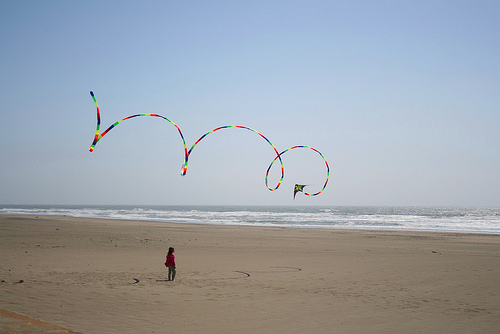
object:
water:
[2, 198, 498, 238]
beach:
[0, 211, 496, 333]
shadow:
[39, 261, 174, 306]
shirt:
[164, 253, 176, 267]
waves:
[0, 202, 499, 233]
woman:
[165, 246, 178, 282]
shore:
[0, 214, 500, 280]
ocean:
[354, 210, 458, 229]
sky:
[2, 0, 500, 209]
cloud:
[4, 27, 499, 204]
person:
[164, 246, 177, 281]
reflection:
[224, 263, 306, 281]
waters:
[193, 204, 495, 211]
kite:
[293, 184, 308, 201]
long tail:
[88, 90, 332, 197]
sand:
[0, 214, 500, 332]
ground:
[0, 210, 498, 334]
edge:
[302, 185, 309, 194]